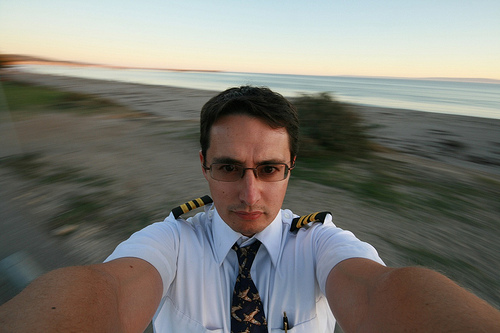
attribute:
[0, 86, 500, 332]
man — moving, spinning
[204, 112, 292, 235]
face — concerned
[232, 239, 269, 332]
tie — black, brown, gold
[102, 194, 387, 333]
shirt — white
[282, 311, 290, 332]
pen — black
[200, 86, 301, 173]
hair — brown, dark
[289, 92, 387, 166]
bush — green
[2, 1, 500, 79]
sky — blue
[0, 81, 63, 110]
grass — green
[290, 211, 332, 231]
epaulette — striped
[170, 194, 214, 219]
epaulette — striped